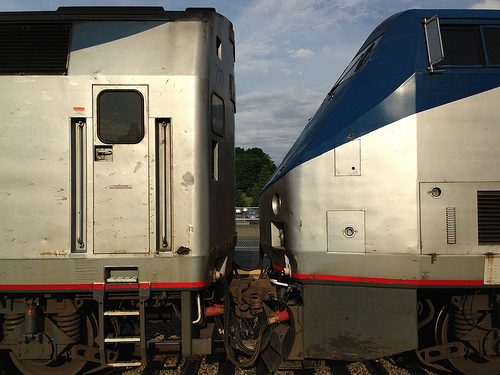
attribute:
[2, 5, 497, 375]
train — silver, blue, edged, plane, tip, steel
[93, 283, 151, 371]
steps — part, silver, stairway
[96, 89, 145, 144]
window — reflective, part, tented, little, black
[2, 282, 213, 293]
line — red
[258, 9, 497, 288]
cabin — grey, blue, edged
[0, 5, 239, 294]
cabin — gray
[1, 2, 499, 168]
sky — cloudy, blue, part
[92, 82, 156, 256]
door — gray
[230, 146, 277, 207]
tree — green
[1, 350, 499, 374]
tracks — gravely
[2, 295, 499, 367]
under-carriage — rusty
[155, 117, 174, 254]
handgrip — assist